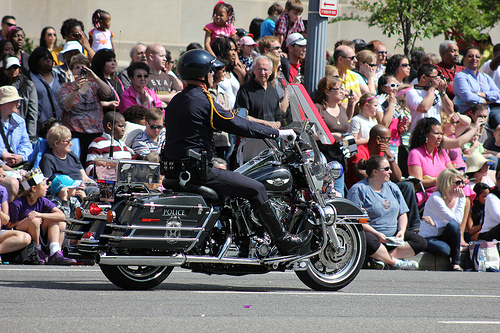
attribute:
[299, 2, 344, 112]
pole — grey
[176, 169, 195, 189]
handcuff — pair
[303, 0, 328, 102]
column — blue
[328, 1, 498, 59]
tree — green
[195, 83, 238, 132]
rope — decorative, yellow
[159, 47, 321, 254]
policeman — motorcycle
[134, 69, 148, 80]
sunglasses — black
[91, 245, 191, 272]
pipe — chrome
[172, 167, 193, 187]
handcuffs — silver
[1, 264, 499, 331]
road — side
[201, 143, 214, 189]
holster — policeman's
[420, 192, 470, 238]
blouse — white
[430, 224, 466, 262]
jeans — blue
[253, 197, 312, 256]
motorcycle boot — black, leather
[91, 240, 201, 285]
pipe — exhaust